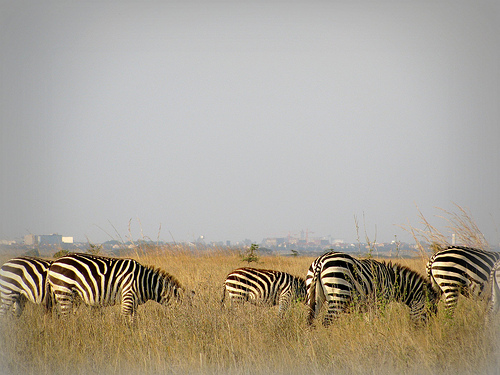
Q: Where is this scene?
A: In a field.